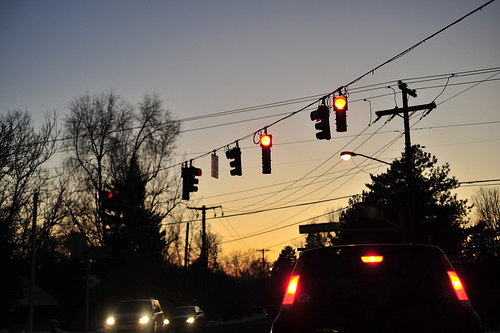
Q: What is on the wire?
A: Lights.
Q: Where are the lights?
A: On the wire.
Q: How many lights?
A: 6.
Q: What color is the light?
A: Yellow.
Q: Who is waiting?
A: People.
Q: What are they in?
A: Cars.